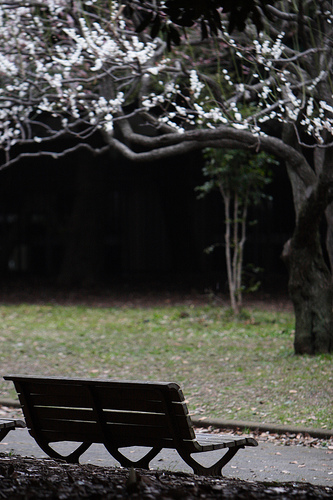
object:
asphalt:
[294, 468, 308, 480]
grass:
[45, 305, 52, 313]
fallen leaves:
[282, 470, 290, 473]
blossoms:
[194, 103, 203, 111]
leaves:
[296, 433, 301, 439]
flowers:
[91, 59, 102, 72]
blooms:
[162, 117, 168, 122]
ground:
[189, 371, 251, 408]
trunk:
[285, 164, 331, 354]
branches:
[111, 137, 132, 155]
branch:
[3, 154, 23, 168]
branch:
[295, 126, 302, 147]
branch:
[259, 10, 270, 29]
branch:
[88, 13, 105, 23]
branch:
[121, 29, 136, 37]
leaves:
[196, 427, 203, 430]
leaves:
[204, 245, 214, 254]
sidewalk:
[0, 462, 332, 497]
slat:
[2, 373, 179, 394]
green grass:
[281, 322, 287, 334]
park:
[0, 0, 332, 500]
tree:
[0, 3, 332, 354]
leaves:
[182, 361, 188, 364]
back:
[0, 375, 193, 447]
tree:
[196, 94, 270, 314]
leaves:
[328, 445, 333, 449]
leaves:
[268, 434, 276, 439]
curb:
[262, 421, 331, 438]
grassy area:
[0, 305, 333, 424]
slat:
[21, 406, 191, 429]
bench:
[1, 371, 258, 486]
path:
[1, 402, 328, 484]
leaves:
[195, 186, 208, 191]